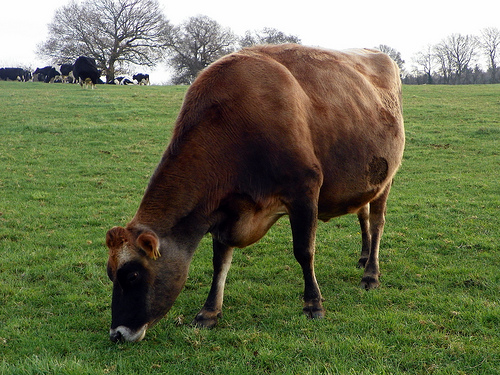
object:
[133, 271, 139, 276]
eye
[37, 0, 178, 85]
bare trees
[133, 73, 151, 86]
cow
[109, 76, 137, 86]
cow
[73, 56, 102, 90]
cow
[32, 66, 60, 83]
cow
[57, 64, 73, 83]
cow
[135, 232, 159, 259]
ear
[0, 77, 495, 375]
grass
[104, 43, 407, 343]
brown cow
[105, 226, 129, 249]
bump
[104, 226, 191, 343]
head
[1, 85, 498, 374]
field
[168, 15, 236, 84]
tree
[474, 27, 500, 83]
trees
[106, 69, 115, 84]
trunk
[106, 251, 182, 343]
face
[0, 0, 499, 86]
sky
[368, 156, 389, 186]
sore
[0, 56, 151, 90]
cow group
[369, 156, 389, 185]
bald spot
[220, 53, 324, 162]
cow fur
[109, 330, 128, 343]
cow snout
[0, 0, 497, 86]
background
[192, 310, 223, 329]
feet